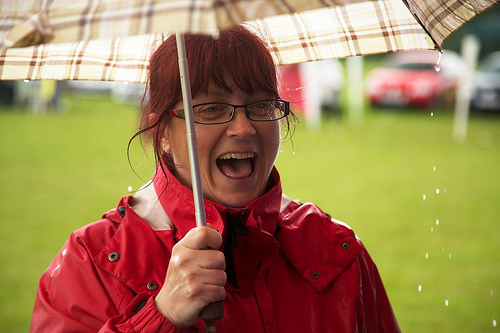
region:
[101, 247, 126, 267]
button on inside of coat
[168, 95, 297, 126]
woman wearing reading glasses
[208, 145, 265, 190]
womans mouth is open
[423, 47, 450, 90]
rain dripping from umbrella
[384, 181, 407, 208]
green grass in field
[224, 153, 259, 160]
teeth in womans mouth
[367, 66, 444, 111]
red car parked in lot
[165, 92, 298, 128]
narrow eyeglasses the lady wears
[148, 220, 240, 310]
lady's hand gripping the umbrella handle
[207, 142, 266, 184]
open mouth with teeth showing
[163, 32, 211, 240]
silver handle of the umbrella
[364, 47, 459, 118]
red car parked in the distance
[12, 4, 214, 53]
edge of brown plaid umbrella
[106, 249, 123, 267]
silver snap on the collar of the red jacket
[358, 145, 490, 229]
green grass behind the lady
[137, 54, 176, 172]
red stringy hair on the side of her head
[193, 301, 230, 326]
bottom of black handle of the umbrella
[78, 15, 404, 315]
a woman standing in the rain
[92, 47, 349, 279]
a woman standing under umbrella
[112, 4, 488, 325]
a woman holding an umbrella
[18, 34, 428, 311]
a woman standing outside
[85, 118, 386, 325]
a woman wearing a jacket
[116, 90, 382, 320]
a woman wearing a red jacket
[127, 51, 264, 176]
a woman wearing glasses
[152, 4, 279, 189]
a woman with red hair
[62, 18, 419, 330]
a woman is outside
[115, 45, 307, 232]
a woman is smiling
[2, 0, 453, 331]
woman standing under an umbrella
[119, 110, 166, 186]
strands of hair hanging down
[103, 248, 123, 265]
button on the jacket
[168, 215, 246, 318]
fingers wrapped around the umbrella rod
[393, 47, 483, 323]
drops of water falling off the umbrella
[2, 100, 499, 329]
green grass on the ground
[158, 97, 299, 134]
thin rimmed glasses on the face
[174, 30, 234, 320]
silver rod attached to the umbrella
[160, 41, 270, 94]
bangs laying on the forehead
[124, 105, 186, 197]
hair over the ear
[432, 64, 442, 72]
drop of rain water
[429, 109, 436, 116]
drop of rain water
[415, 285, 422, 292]
drop of rain water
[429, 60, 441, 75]
clear falling rain drop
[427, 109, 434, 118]
clear falling rain drop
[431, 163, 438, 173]
clear falling rain drop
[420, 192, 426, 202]
clear falling rain drop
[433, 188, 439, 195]
clear falling rain drop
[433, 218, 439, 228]
clear falling rain drop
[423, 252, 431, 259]
clear falling rain drop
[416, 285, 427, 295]
clear falling rain drop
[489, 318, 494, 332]
clear falling rain drop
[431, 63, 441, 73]
clear falling rain drop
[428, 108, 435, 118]
clear falling rain drop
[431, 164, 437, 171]
clear falling rain drop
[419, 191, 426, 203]
clear falling rain drop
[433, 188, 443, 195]
clear falling rain drop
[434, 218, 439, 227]
clear falling rain drop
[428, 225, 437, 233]
clear falling rain drop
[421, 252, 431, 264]
clear falling rain drop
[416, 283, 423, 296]
clear falling rain drop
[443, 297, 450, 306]
clear falling rain drop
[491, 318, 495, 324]
A drop of water.